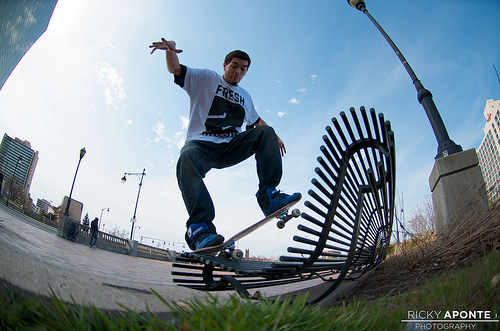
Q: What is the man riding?
A: A skateboard.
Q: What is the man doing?
A: A trick.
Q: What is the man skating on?
A: A bench.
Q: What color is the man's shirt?
A: White.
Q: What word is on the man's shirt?
A: Fresh.